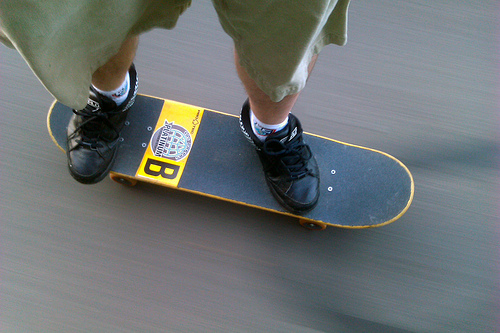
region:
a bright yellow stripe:
[128, 81, 229, 216]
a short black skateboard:
[31, 66, 428, 273]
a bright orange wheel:
[293, 207, 340, 235]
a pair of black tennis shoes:
[38, 52, 338, 212]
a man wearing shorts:
[12, 2, 365, 234]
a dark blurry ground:
[26, 85, 481, 318]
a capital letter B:
[131, 147, 188, 187]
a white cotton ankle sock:
[236, 103, 322, 150]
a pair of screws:
[320, 161, 345, 200]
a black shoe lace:
[254, 122, 329, 194]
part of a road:
[374, 92, 431, 167]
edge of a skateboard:
[207, 188, 275, 222]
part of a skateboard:
[164, 118, 201, 165]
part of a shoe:
[281, 174, 310, 211]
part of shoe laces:
[263, 120, 308, 166]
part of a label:
[157, 127, 198, 169]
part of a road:
[162, 228, 222, 287]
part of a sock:
[259, 127, 279, 144]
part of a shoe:
[53, 147, 75, 178]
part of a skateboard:
[188, 162, 220, 200]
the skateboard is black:
[42, 74, 415, 245]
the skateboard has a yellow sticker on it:
[132, 90, 204, 205]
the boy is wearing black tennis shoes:
[47, 70, 413, 240]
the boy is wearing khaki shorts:
[0, 2, 347, 111]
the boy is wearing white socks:
[80, 68, 302, 149]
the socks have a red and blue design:
[246, 120, 282, 146]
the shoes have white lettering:
[268, 126, 304, 153]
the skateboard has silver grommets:
[325, 158, 337, 203]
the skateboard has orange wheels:
[107, 165, 330, 238]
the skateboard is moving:
[42, 62, 417, 247]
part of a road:
[343, 262, 412, 291]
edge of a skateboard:
[347, 213, 387, 240]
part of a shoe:
[297, 195, 337, 215]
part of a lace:
[278, 134, 302, 179]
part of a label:
[154, 155, 179, 177]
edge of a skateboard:
[222, 188, 263, 215]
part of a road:
[119, 236, 218, 285]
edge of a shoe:
[79, 167, 109, 186]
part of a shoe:
[267, 146, 314, 175]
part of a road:
[185, 261, 244, 312]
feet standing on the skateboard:
[69, 76, 316, 211]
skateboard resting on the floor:
[45, 80, 415, 232]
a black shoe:
[239, 98, 324, 211]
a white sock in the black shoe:
[245, 98, 296, 143]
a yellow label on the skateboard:
[136, 95, 204, 190]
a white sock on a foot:
[246, 95, 294, 145]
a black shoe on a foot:
[239, 95, 318, 211]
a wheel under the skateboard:
[296, 212, 327, 232]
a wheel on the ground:
[111, 170, 136, 186]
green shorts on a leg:
[214, 0, 349, 101]